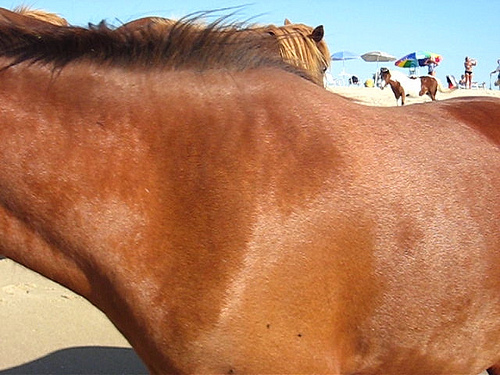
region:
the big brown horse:
[2, 15, 497, 373]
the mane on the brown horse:
[7, 15, 279, 70]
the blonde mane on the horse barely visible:
[276, 25, 331, 75]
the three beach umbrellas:
[334, 47, 442, 70]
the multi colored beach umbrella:
[396, 50, 442, 70]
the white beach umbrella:
[362, 50, 394, 65]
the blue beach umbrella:
[330, 48, 360, 63]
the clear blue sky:
[330, 0, 497, 42]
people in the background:
[425, 53, 498, 88]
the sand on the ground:
[3, 280, 55, 355]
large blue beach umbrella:
[328, 45, 352, 67]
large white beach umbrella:
[370, 47, 391, 68]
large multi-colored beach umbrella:
[402, 47, 439, 67]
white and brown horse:
[384, 72, 451, 104]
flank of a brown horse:
[82, 102, 467, 354]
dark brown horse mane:
[20, 17, 314, 106]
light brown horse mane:
[269, 20, 326, 73]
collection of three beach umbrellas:
[332, 42, 434, 84]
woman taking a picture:
[462, 55, 479, 87]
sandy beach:
[8, 288, 88, 373]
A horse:
[182, 182, 339, 284]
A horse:
[207, 221, 282, 332]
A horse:
[222, 210, 339, 352]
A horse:
[250, 256, 305, 312]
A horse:
[291, 254, 302, 271]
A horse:
[294, 228, 354, 310]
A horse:
[259, 191, 324, 303]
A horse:
[282, 221, 339, 369]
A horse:
[254, 234, 296, 301]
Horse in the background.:
[265, 27, 371, 98]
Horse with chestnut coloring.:
[131, 82, 423, 355]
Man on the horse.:
[61, 34, 303, 116]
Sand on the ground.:
[20, 305, 75, 350]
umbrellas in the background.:
[338, 40, 497, 152]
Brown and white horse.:
[340, 20, 473, 141]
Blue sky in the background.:
[345, 15, 455, 113]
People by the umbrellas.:
[362, 47, 473, 109]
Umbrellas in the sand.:
[335, 52, 447, 107]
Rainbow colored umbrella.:
[355, 25, 446, 69]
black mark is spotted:
[286, 326, 304, 342]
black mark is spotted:
[289, 324, 309, 348]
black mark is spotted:
[299, 336, 314, 341]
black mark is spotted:
[295, 325, 313, 362]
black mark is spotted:
[292, 334, 306, 347]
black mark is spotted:
[292, 314, 302, 356]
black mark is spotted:
[298, 330, 310, 342]